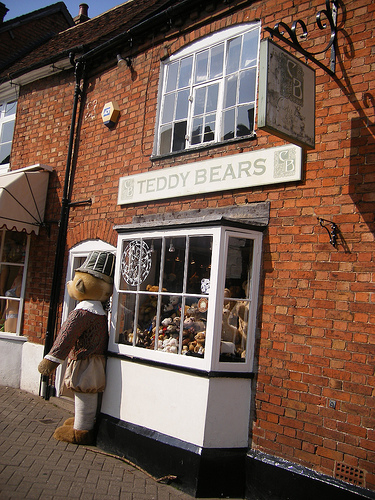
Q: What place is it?
A: It is a shop.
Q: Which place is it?
A: It is a shop.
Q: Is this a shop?
A: Yes, it is a shop.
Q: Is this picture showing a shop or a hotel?
A: It is showing a shop.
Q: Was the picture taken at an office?
A: No, the picture was taken in a shop.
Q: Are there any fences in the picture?
A: No, there are no fences.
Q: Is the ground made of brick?
A: Yes, the ground is made of brick.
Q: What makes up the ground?
A: The ground is made of brick.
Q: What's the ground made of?
A: The ground is made of brick.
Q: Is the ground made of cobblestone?
A: No, the ground is made of brick.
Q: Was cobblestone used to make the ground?
A: No, the ground is made of brick.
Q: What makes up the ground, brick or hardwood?
A: The ground is made of brick.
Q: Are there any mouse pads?
A: No, there are no mouse pads.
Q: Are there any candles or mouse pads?
A: No, there are no mouse pads or candles.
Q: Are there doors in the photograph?
A: Yes, there is a door.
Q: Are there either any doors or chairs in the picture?
A: Yes, there is a door.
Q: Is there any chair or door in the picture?
A: Yes, there is a door.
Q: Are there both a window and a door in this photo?
A: Yes, there are both a door and a window.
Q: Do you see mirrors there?
A: No, there are no mirrors.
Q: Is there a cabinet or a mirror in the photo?
A: No, there are no mirrors or cabinets.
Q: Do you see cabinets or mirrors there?
A: No, there are no mirrors or cabinets.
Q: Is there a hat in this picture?
A: Yes, there is a hat.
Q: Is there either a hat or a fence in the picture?
A: Yes, there is a hat.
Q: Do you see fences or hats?
A: Yes, there is a hat.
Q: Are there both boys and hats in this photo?
A: No, there is a hat but no boys.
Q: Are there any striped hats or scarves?
A: Yes, there is a striped hat.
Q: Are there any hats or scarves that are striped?
A: Yes, the hat is striped.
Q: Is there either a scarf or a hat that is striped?
A: Yes, the hat is striped.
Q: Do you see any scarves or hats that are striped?
A: Yes, the hat is striped.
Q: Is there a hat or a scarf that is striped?
A: Yes, the hat is striped.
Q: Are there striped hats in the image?
A: Yes, there is a striped hat.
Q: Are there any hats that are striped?
A: Yes, there is a hat that is striped.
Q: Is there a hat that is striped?
A: Yes, there is a hat that is striped.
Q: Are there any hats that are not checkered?
A: Yes, there is a striped hat.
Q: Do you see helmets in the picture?
A: No, there are no helmets.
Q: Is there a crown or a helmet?
A: No, there are no helmets or crowns.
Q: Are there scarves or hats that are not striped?
A: No, there is a hat but it is striped.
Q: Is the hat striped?
A: Yes, the hat is striped.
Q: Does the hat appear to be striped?
A: Yes, the hat is striped.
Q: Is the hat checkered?
A: No, the hat is striped.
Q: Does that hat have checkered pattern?
A: No, the hat is striped.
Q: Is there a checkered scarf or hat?
A: No, there is a hat but it is striped.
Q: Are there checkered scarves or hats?
A: No, there is a hat but it is striped.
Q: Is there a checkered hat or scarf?
A: No, there is a hat but it is striped.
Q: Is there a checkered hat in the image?
A: No, there is a hat but it is striped.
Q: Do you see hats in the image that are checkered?
A: No, there is a hat but it is striped.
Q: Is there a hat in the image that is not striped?
A: No, there is a hat but it is striped.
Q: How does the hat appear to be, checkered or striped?
A: The hat is striped.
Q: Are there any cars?
A: No, there are no cars.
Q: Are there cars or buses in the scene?
A: No, there are no cars or buses.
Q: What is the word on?
A: The word is on the sign.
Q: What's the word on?
A: The word is on the sign.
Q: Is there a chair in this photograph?
A: No, there are no chairs.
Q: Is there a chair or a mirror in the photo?
A: No, there are no chairs or mirrors.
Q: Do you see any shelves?
A: No, there are no shelves.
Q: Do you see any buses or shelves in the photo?
A: No, there are no shelves or buses.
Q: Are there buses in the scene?
A: No, there are no buses.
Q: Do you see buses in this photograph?
A: No, there are no buses.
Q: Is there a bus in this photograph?
A: No, there are no buses.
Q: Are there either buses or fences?
A: No, there are no buses or fences.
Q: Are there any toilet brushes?
A: No, there are no toilet brushes.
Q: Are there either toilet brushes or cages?
A: No, there are no toilet brushes or cages.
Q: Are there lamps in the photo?
A: Yes, there is a lamp.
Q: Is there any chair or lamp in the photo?
A: Yes, there is a lamp.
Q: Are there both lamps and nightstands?
A: No, there is a lamp but no nightstands.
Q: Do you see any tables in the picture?
A: No, there are no tables.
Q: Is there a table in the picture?
A: No, there are no tables.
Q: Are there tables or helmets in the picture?
A: No, there are no tables or helmets.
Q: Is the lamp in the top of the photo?
A: Yes, the lamp is in the top of the image.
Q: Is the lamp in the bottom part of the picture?
A: No, the lamp is in the top of the image.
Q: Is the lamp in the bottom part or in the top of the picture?
A: The lamp is in the top of the image.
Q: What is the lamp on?
A: The lamp is on the wall.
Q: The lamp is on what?
A: The lamp is on the wall.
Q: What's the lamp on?
A: The lamp is on the wall.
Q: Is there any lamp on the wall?
A: Yes, there is a lamp on the wall.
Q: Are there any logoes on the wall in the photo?
A: No, there is a lamp on the wall.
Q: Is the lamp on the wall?
A: Yes, the lamp is on the wall.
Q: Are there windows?
A: Yes, there is a window.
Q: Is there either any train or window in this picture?
A: Yes, there is a window.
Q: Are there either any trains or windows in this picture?
A: Yes, there is a window.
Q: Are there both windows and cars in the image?
A: No, there is a window but no cars.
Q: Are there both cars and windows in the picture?
A: No, there is a window but no cars.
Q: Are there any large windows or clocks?
A: Yes, there is a large window.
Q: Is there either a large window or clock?
A: Yes, there is a large window.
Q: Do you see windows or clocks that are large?
A: Yes, the window is large.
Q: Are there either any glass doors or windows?
A: Yes, there is a glass window.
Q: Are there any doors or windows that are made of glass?
A: Yes, the window is made of glass.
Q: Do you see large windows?
A: Yes, there is a large window.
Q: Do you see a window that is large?
A: Yes, there is a window that is large.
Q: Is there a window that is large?
A: Yes, there is a window that is large.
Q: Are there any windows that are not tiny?
A: Yes, there is a large window.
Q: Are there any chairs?
A: No, there are no chairs.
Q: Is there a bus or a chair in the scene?
A: No, there are no chairs or buses.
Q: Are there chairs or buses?
A: No, there are no chairs or buses.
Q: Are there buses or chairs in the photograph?
A: No, there are no chairs or buses.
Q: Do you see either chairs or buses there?
A: No, there are no chairs or buses.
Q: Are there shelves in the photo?
A: No, there are no shelves.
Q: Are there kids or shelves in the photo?
A: No, there are no shelves or kids.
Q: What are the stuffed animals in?
A: The stuffed animals are in the window.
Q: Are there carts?
A: No, there are no carts.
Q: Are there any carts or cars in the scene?
A: No, there are no carts or cars.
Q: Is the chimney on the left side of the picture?
A: Yes, the chimney is on the left of the image.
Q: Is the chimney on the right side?
A: No, the chimney is on the left of the image.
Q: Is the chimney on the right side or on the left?
A: The chimney is on the left of the image.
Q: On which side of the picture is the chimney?
A: The chimney is on the left of the image.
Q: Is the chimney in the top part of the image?
A: Yes, the chimney is in the top of the image.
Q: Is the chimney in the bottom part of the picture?
A: No, the chimney is in the top of the image.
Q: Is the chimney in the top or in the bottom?
A: The chimney is in the top of the image.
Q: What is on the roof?
A: The chimney is on the roof.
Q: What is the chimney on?
A: The chimney is on the roof.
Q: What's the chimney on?
A: The chimney is on the roof.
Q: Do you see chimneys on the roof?
A: Yes, there is a chimney on the roof.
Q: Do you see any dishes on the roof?
A: No, there is a chimney on the roof.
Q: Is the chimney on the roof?
A: Yes, the chimney is on the roof.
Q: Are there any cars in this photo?
A: No, there are no cars.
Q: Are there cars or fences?
A: No, there are no cars or fences.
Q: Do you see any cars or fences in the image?
A: No, there are no cars or fences.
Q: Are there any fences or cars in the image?
A: No, there are no cars or fences.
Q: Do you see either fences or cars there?
A: No, there are no cars or fences.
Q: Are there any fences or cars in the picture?
A: No, there are no cars or fences.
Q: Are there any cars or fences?
A: No, there are no cars or fences.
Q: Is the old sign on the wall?
A: Yes, the sign is on the wall.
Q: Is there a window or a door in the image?
A: Yes, there is a window.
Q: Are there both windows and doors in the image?
A: Yes, there are both a window and doors.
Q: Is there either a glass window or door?
A: Yes, there is a glass window.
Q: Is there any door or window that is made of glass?
A: Yes, the window is made of glass.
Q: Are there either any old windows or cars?
A: Yes, there is an old window.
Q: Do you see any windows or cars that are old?
A: Yes, the window is old.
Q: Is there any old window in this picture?
A: Yes, there is an old window.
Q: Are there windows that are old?
A: Yes, there is a window that is old.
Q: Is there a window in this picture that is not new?
A: Yes, there is a old window.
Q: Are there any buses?
A: No, there are no buses.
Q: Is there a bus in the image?
A: No, there are no buses.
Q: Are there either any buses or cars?
A: No, there are no buses or cars.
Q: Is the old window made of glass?
A: Yes, the window is made of glass.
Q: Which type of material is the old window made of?
A: The window is made of glass.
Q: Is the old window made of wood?
A: No, the window is made of glass.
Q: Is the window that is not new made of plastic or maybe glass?
A: The window is made of glass.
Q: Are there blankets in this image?
A: No, there are no blankets.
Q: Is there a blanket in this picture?
A: No, there are no blankets.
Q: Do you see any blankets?
A: No, there are no blankets.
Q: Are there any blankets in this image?
A: No, there are no blankets.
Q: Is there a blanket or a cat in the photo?
A: No, there are no blankets or cats.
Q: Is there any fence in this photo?
A: No, there are no fences.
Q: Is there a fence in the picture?
A: No, there are no fences.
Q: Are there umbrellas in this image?
A: No, there are no umbrellas.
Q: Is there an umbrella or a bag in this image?
A: No, there are no umbrellas or bags.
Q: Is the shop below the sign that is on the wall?
A: Yes, the shop is below the sign.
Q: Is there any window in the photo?
A: Yes, there is a window.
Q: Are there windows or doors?
A: Yes, there is a window.